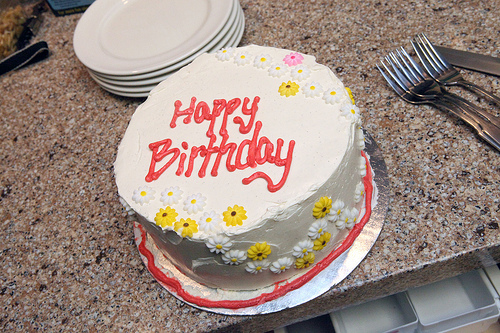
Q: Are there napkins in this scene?
A: No, there are no napkins.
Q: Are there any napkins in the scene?
A: No, there are no napkins.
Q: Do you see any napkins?
A: No, there are no napkins.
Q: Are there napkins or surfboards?
A: No, there are no napkins or surfboards.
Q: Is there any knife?
A: Yes, there is a knife.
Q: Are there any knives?
A: Yes, there is a knife.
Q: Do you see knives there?
A: Yes, there is a knife.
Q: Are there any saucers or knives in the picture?
A: Yes, there is a knife.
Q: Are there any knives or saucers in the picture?
A: Yes, there is a knife.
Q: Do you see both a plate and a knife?
A: Yes, there are both a knife and a plate.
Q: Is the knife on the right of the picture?
A: Yes, the knife is on the right of the image.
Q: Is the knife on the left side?
A: No, the knife is on the right of the image.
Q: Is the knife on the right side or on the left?
A: The knife is on the right of the image.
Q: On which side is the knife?
A: The knife is on the right of the image.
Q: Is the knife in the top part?
A: Yes, the knife is in the top of the image.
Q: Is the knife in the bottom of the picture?
A: No, the knife is in the top of the image.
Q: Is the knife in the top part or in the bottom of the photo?
A: The knife is in the top of the image.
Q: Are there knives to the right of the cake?
A: Yes, there is a knife to the right of the cake.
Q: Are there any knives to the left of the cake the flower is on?
A: No, the knife is to the right of the cake.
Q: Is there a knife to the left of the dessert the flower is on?
A: No, the knife is to the right of the cake.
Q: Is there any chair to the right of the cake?
A: No, there is a knife to the right of the cake.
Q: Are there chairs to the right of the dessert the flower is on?
A: No, there is a knife to the right of the cake.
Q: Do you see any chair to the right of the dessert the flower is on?
A: No, there is a knife to the right of the cake.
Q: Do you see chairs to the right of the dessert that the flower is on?
A: No, there is a knife to the right of the cake.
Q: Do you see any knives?
A: Yes, there is a knife.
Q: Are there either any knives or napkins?
A: Yes, there is a knife.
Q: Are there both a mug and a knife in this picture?
A: No, there is a knife but no mugs.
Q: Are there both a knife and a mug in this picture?
A: No, there is a knife but no mugs.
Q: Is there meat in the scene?
A: No, there is no meat.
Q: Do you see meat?
A: No, there is no meat.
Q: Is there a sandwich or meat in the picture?
A: No, there are no meat or sandwiches.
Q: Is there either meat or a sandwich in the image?
A: No, there are no meat or sandwiches.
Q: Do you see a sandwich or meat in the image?
A: No, there are no meat or sandwiches.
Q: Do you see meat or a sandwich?
A: No, there are no meat or sandwiches.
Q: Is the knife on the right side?
A: Yes, the knife is on the right of the image.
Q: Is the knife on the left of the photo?
A: No, the knife is on the right of the image.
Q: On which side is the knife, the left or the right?
A: The knife is on the right of the image.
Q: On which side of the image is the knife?
A: The knife is on the right of the image.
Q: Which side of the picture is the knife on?
A: The knife is on the right of the image.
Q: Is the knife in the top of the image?
A: Yes, the knife is in the top of the image.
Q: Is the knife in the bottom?
A: No, the knife is in the top of the image.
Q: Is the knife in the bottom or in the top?
A: The knife is in the top of the image.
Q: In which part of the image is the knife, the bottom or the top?
A: The knife is in the top of the image.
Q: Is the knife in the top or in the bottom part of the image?
A: The knife is in the top of the image.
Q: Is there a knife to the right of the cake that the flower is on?
A: Yes, there is a knife to the right of the cake.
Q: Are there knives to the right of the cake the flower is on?
A: Yes, there is a knife to the right of the cake.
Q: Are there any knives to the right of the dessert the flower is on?
A: Yes, there is a knife to the right of the cake.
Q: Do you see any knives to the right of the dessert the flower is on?
A: Yes, there is a knife to the right of the cake.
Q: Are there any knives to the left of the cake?
A: No, the knife is to the right of the cake.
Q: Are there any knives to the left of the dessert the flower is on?
A: No, the knife is to the right of the cake.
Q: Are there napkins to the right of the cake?
A: No, there is a knife to the right of the cake.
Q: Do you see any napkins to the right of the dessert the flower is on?
A: No, there is a knife to the right of the cake.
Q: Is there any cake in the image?
A: Yes, there is a cake.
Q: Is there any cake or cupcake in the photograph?
A: Yes, there is a cake.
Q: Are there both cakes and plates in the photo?
A: Yes, there are both a cake and plates.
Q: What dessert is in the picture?
A: The dessert is a cake.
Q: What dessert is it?
A: The dessert is a cake.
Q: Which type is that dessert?
A: That is a cake.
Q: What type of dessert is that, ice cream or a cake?
A: That is a cake.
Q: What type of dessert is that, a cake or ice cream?
A: That is a cake.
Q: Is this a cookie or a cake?
A: This is a cake.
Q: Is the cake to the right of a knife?
A: No, the cake is to the left of a knife.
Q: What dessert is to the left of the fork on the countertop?
A: The dessert is a cake.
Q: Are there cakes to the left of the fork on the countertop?
A: Yes, there is a cake to the left of the fork.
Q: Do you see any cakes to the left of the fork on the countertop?
A: Yes, there is a cake to the left of the fork.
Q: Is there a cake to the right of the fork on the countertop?
A: No, the cake is to the left of the fork.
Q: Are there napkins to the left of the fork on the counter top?
A: No, there is a cake to the left of the fork.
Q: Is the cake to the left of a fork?
A: Yes, the cake is to the left of a fork.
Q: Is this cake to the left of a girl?
A: No, the cake is to the left of a fork.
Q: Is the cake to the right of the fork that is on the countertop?
A: No, the cake is to the left of the fork.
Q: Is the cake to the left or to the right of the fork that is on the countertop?
A: The cake is to the left of the fork.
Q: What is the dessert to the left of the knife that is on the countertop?
A: The dessert is a cake.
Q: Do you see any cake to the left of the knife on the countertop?
A: Yes, there is a cake to the left of the knife.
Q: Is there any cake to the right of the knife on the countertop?
A: No, the cake is to the left of the knife.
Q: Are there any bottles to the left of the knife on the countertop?
A: No, there is a cake to the left of the knife.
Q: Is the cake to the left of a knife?
A: Yes, the cake is to the left of a knife.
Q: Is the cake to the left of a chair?
A: No, the cake is to the left of a knife.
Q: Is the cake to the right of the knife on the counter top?
A: No, the cake is to the left of the knife.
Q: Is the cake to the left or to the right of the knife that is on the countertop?
A: The cake is to the left of the knife.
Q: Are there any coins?
A: No, there are no coins.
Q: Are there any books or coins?
A: No, there are no coins or books.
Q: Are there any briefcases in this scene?
A: No, there are no briefcases.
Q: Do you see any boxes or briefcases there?
A: No, there are no briefcases or boxes.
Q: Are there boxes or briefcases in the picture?
A: No, there are no briefcases or boxes.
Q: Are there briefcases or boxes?
A: No, there are no briefcases or boxes.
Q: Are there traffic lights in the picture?
A: No, there are no traffic lights.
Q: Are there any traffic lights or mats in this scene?
A: No, there are no traffic lights or mats.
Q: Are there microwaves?
A: No, there are no microwaves.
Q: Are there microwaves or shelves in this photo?
A: No, there are no microwaves or shelves.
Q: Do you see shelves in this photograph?
A: No, there are no shelves.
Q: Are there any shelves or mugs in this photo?
A: No, there are no shelves or mugs.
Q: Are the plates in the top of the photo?
A: Yes, the plates are in the top of the image.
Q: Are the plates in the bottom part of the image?
A: No, the plates are in the top of the image.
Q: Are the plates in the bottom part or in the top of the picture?
A: The plates are in the top of the image.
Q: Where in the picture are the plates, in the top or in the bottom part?
A: The plates are in the top of the image.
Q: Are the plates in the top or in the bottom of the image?
A: The plates are in the top of the image.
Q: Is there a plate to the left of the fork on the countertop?
A: Yes, there are plates to the left of the fork.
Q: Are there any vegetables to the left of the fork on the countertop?
A: No, there are plates to the left of the fork.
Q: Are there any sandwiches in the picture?
A: No, there are no sandwiches.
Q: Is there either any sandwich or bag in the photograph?
A: No, there are no sandwiches or bags.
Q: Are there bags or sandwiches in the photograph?
A: No, there are no sandwiches or bags.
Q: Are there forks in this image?
A: Yes, there is a fork.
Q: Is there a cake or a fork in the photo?
A: Yes, there is a fork.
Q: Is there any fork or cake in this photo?
A: Yes, there is a fork.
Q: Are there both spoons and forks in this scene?
A: No, there is a fork but no spoons.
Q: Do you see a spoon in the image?
A: No, there are no spoons.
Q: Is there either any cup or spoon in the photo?
A: No, there are no spoons or cups.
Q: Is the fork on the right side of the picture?
A: Yes, the fork is on the right of the image.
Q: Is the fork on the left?
A: No, the fork is on the right of the image.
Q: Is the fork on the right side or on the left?
A: The fork is on the right of the image.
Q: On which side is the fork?
A: The fork is on the right of the image.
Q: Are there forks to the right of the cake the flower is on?
A: Yes, there is a fork to the right of the cake.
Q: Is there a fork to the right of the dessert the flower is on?
A: Yes, there is a fork to the right of the cake.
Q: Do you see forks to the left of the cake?
A: No, the fork is to the right of the cake.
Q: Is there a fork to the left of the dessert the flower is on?
A: No, the fork is to the right of the cake.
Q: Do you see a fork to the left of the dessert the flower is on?
A: No, the fork is to the right of the cake.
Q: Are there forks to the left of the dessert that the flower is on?
A: No, the fork is to the right of the cake.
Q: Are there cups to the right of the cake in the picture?
A: No, there is a fork to the right of the cake.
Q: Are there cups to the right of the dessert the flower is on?
A: No, there is a fork to the right of the cake.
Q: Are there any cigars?
A: No, there are no cigars.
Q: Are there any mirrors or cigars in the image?
A: No, there are no cigars or mirrors.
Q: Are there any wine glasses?
A: No, there are no wine glasses.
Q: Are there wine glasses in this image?
A: No, there are no wine glasses.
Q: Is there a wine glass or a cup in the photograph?
A: No, there are no wine glasses or cups.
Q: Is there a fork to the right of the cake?
A: Yes, there are forks to the right of the cake.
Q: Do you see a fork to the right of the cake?
A: Yes, there are forks to the right of the cake.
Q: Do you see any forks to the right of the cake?
A: Yes, there are forks to the right of the cake.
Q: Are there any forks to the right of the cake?
A: Yes, there are forks to the right of the cake.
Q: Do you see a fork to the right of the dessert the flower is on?
A: Yes, there are forks to the right of the cake.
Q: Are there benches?
A: No, there are no benches.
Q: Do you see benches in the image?
A: No, there are no benches.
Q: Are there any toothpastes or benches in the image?
A: No, there are no benches or toothpastes.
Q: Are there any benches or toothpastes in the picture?
A: No, there are no benches or toothpastes.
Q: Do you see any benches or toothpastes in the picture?
A: No, there are no benches or toothpastes.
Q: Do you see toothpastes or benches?
A: No, there are no benches or toothpastes.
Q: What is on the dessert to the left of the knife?
A: The flower is on the cake.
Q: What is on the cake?
A: The flower is on the cake.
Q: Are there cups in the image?
A: No, there are no cups.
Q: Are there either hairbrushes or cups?
A: No, there are no cups or hairbrushes.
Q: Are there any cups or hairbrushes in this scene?
A: No, there are no cups or hairbrushes.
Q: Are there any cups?
A: No, there are no cups.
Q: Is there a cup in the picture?
A: No, there are no cups.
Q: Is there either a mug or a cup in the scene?
A: No, there are no cups or mugs.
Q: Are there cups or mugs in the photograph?
A: No, there are no cups or mugs.